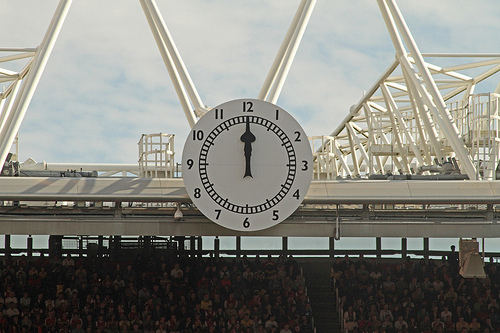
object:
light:
[455, 237, 490, 280]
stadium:
[0, 230, 500, 330]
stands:
[1, 253, 499, 330]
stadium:
[0, 158, 497, 331]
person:
[170, 259, 184, 279]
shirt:
[170, 270, 182, 277]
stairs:
[298, 257, 350, 329]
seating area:
[1, 251, 496, 329]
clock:
[173, 90, 319, 245]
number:
[285, 187, 315, 203]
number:
[238, 215, 253, 230]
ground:
[311, 153, 336, 187]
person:
[442, 242, 463, 267]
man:
[412, 249, 499, 301]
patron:
[265, 312, 277, 328]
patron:
[240, 317, 255, 327]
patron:
[222, 290, 243, 311]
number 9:
[184, 156, 197, 173]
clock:
[180, 87, 323, 240]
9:
[184, 158, 196, 174]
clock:
[178, 92, 313, 234]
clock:
[135, 59, 372, 271]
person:
[447, 242, 457, 274]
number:
[212, 206, 224, 221]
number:
[272, 204, 294, 232]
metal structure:
[1, 0, 499, 200]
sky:
[33, 8, 330, 145]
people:
[354, 262, 426, 329]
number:
[283, 130, 309, 150]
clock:
[184, 98, 311, 235]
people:
[35, 265, 365, 325]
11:
[209, 105, 230, 122]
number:
[190, 129, 205, 141]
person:
[170, 263, 182, 278]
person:
[380, 304, 394, 321]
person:
[381, 274, 397, 292]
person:
[431, 275, 444, 291]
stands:
[1, 246, 484, 330]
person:
[200, 293, 212, 309]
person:
[53, 292, 67, 305]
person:
[440, 306, 454, 321]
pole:
[459, 235, 485, 285]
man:
[448, 244, 460, 265]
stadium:
[2, 2, 484, 330]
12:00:
[240, 100, 255, 179]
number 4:
[291, 188, 301, 201]